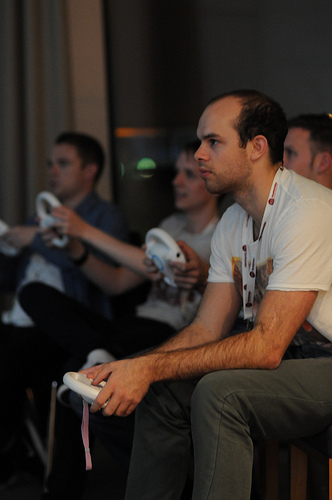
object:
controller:
[144, 228, 186, 288]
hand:
[170, 239, 209, 290]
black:
[78, 245, 90, 270]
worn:
[70, 245, 88, 267]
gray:
[220, 454, 233, 498]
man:
[0, 129, 128, 498]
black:
[68, 308, 97, 338]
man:
[17, 138, 219, 422]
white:
[280, 192, 328, 254]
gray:
[220, 17, 253, 47]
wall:
[197, 0, 330, 122]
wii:
[144, 225, 186, 288]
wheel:
[145, 226, 187, 287]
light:
[137, 157, 155, 179]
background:
[0, 0, 332, 500]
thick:
[64, 0, 114, 204]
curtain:
[0, 3, 74, 225]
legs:
[290, 443, 306, 500]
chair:
[252, 429, 332, 500]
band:
[69, 248, 88, 271]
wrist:
[70, 244, 88, 271]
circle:
[149, 254, 164, 272]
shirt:
[2, 196, 123, 326]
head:
[194, 89, 289, 196]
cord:
[80, 397, 91, 471]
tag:
[231, 257, 273, 307]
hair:
[228, 90, 288, 167]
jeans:
[126, 345, 332, 500]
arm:
[149, 227, 321, 385]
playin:
[0, 0, 331, 500]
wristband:
[81, 398, 93, 472]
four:
[0, 87, 330, 500]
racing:
[35, 189, 195, 287]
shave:
[204, 150, 255, 195]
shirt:
[207, 166, 332, 347]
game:
[62, 371, 107, 410]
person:
[77, 91, 332, 500]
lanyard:
[241, 167, 283, 321]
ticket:
[241, 318, 254, 334]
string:
[80, 396, 91, 473]